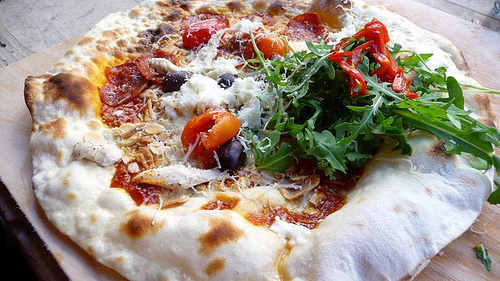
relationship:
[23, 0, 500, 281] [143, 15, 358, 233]
baked pizza has cheese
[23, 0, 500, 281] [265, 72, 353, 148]
baked pizza has argula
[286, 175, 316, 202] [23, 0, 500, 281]
topping on baked pizza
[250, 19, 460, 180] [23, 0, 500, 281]
topping on baked pizza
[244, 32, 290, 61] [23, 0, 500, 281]
topping on a baked pizza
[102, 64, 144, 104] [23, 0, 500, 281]
topping on a baked pizza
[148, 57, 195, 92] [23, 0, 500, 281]
topping on a baked pizza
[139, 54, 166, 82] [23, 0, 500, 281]
topping on a baked pizza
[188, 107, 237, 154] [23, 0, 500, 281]
topping on a baked pizza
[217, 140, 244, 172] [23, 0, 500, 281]
topping on a baked pizza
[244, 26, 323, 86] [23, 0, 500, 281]
topping on a baked pizza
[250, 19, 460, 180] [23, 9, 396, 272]
topping on a pizza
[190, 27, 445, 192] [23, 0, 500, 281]
truck on baked pizza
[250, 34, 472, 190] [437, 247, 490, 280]
green vegetable on table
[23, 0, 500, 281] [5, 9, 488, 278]
baked pizza on table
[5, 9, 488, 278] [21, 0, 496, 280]
table with a baked pizza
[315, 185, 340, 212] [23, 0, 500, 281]
sauce on a baked pizza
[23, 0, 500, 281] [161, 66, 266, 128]
baked pizza with cheese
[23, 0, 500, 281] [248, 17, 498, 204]
baked pizza with vegetable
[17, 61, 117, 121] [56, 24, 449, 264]
burnt end on pizza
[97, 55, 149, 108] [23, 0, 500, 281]
meat on baked pizza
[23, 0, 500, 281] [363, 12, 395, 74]
baked pizza has pepper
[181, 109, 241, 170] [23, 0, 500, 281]
topping on baked pizza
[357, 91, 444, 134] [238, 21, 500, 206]
leafs on green vegetable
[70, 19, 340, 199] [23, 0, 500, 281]
cheese on baked pizza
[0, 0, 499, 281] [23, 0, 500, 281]
table with baked pizza